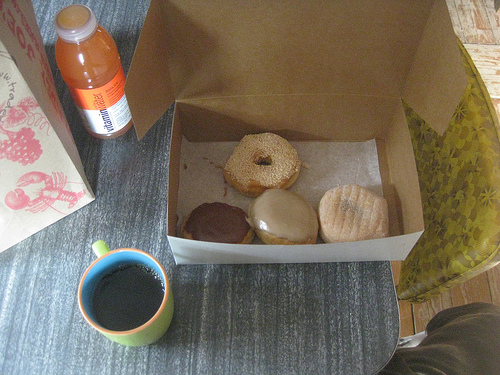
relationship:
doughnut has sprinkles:
[221, 132, 298, 196] [232, 146, 251, 172]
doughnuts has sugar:
[318, 181, 389, 244] [323, 207, 335, 227]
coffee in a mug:
[93, 262, 162, 333] [75, 239, 176, 349]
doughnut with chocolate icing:
[182, 201, 255, 245] [191, 206, 246, 243]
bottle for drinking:
[54, 6, 133, 141] [62, 7, 106, 42]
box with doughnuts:
[124, 1, 483, 264] [178, 130, 389, 245]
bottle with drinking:
[54, 6, 133, 141] [53, 3, 135, 140]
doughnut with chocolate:
[182, 201, 255, 245] [201, 216, 227, 235]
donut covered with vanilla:
[245, 189, 319, 248] [268, 212, 300, 234]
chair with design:
[391, 28, 498, 302] [438, 158, 499, 203]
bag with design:
[1, 1, 95, 255] [1, 105, 55, 206]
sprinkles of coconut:
[232, 146, 251, 172] [266, 138, 281, 150]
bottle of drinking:
[54, 6, 133, 141] [53, 3, 135, 140]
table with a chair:
[1, 1, 400, 374] [391, 28, 498, 302]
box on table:
[124, 1, 483, 264] [1, 1, 400, 374]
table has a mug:
[1, 1, 400, 374] [75, 239, 176, 349]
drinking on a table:
[53, 3, 135, 140] [1, 1, 400, 374]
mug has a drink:
[75, 239, 176, 349] [75, 238, 175, 347]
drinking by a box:
[53, 3, 135, 140] [124, 1, 483, 264]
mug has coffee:
[75, 239, 176, 349] [93, 262, 162, 333]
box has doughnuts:
[124, 1, 483, 264] [178, 130, 389, 245]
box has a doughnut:
[124, 1, 483, 264] [182, 201, 255, 245]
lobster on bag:
[4, 167, 89, 215] [1, 1, 95, 255]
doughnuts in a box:
[178, 130, 389, 245] [124, 1, 483, 264]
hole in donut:
[253, 151, 272, 166] [221, 132, 298, 196]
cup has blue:
[75, 239, 176, 349] [103, 251, 140, 261]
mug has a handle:
[75, 239, 176, 349] [89, 240, 113, 260]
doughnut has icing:
[182, 201, 255, 245] [218, 216, 236, 234]